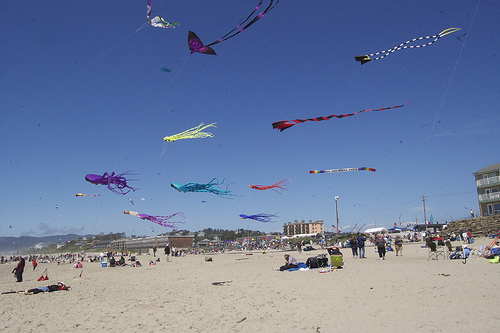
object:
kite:
[143, 3, 179, 30]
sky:
[0, 0, 499, 238]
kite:
[188, 0, 281, 57]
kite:
[354, 24, 463, 65]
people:
[349, 236, 359, 259]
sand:
[0, 234, 500, 333]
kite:
[273, 100, 406, 132]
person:
[22, 282, 68, 296]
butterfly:
[187, 0, 280, 57]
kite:
[163, 122, 219, 143]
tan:
[257, 272, 298, 302]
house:
[472, 160, 500, 218]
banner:
[308, 164, 377, 175]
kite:
[241, 212, 279, 224]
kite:
[170, 178, 245, 203]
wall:
[442, 215, 500, 236]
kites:
[124, 208, 197, 230]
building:
[283, 217, 324, 237]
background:
[0, 0, 499, 333]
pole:
[334, 194, 342, 234]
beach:
[2, 240, 499, 332]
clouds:
[20, 219, 86, 237]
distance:
[2, 224, 142, 251]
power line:
[424, 190, 479, 197]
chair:
[427, 238, 447, 262]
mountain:
[0, 234, 82, 250]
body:
[276, 254, 299, 271]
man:
[275, 254, 302, 271]